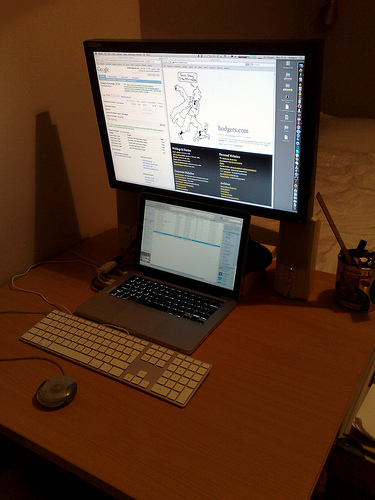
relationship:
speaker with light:
[272, 217, 326, 249] [277, 252, 298, 277]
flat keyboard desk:
[29, 298, 224, 434] [242, 348, 294, 419]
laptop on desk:
[124, 188, 255, 358] [242, 348, 294, 419]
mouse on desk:
[20, 356, 108, 430] [242, 348, 294, 419]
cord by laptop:
[16, 257, 59, 313] [124, 188, 255, 358]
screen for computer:
[64, 47, 309, 212] [124, 188, 255, 358]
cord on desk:
[16, 257, 59, 313] [242, 348, 294, 419]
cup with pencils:
[339, 259, 374, 304] [325, 220, 374, 263]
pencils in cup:
[316, 192, 354, 265] [339, 259, 374, 304]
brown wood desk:
[244, 330, 271, 351] [242, 348, 294, 419]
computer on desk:
[62, 36, 277, 297] [242, 348, 294, 419]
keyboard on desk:
[37, 312, 205, 400] [242, 348, 294, 419]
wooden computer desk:
[261, 326, 305, 346] [242, 348, 294, 419]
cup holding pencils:
[339, 259, 374, 304] [325, 220, 374, 263]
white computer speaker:
[128, 80, 165, 96] [272, 217, 326, 249]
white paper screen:
[128, 80, 165, 96] [64, 47, 309, 212]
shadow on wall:
[32, 134, 74, 190] [21, 32, 56, 55]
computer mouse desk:
[62, 36, 277, 297] [242, 348, 294, 419]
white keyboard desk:
[128, 80, 165, 96] [242, 348, 294, 419]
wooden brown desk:
[261, 326, 305, 346] [242, 348, 294, 419]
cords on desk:
[16, 257, 59, 313] [242, 348, 294, 419]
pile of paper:
[336, 397, 374, 454] [129, 82, 165, 119]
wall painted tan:
[21, 32, 56, 55] [19, 19, 83, 37]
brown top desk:
[244, 330, 271, 351] [242, 348, 294, 419]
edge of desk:
[17, 454, 114, 483] [242, 348, 294, 419]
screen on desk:
[64, 47, 309, 212] [242, 348, 294, 419]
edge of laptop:
[17, 454, 114, 483] [124, 188, 255, 358]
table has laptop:
[37, 416, 170, 491] [124, 188, 255, 358]